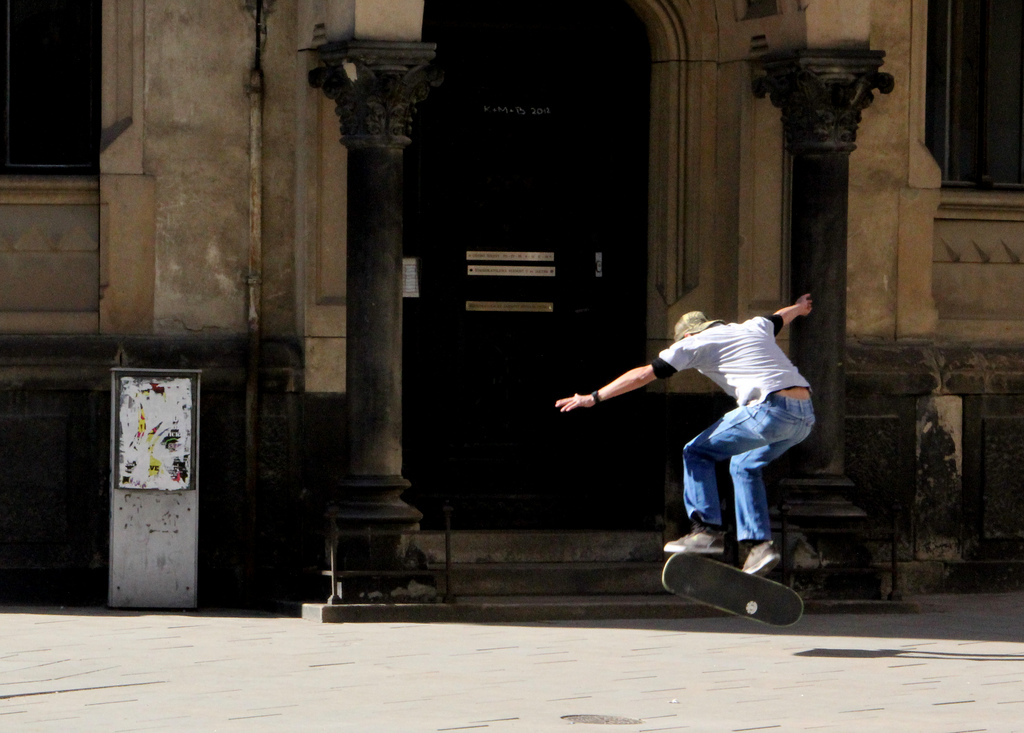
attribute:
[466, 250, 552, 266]
name plate — gold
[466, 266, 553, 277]
name plate — gold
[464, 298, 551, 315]
name plate — gold